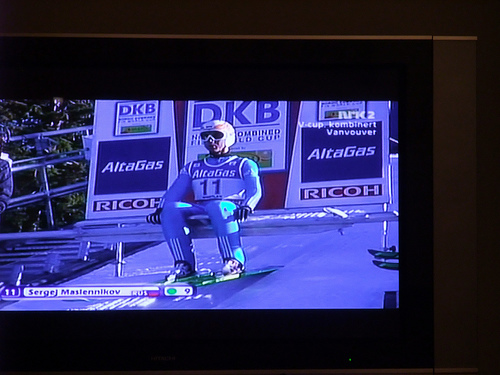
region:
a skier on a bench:
[96, 115, 314, 300]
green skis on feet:
[128, 233, 341, 313]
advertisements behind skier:
[96, 101, 419, 207]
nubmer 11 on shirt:
[186, 177, 238, 213]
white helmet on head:
[193, 110, 236, 148]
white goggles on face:
[198, 129, 232, 143]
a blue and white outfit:
[149, 144, 305, 296]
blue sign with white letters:
[88, 133, 175, 196]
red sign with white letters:
[300, 175, 387, 222]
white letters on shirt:
[185, 165, 239, 180]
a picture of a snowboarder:
[6, 83, 441, 298]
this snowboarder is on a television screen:
[7, 80, 423, 327]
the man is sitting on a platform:
[125, 102, 271, 282]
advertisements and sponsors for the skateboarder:
[91, 97, 396, 217]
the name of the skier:
[1, 275, 206, 295]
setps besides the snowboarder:
[2, 126, 120, 261]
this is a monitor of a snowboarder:
[11, 40, 472, 363]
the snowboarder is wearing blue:
[125, 130, 280, 296]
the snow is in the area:
[82, 253, 357, 311]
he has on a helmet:
[186, 115, 258, 162]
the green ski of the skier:
[155, 272, 202, 288]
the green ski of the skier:
[187, 262, 277, 288]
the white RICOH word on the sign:
[92, 198, 159, 211]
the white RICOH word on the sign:
[299, 181, 383, 203]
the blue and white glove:
[147, 208, 163, 223]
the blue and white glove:
[233, 205, 250, 220]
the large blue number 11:
[198, 176, 221, 198]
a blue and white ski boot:
[168, 260, 190, 281]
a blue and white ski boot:
[218, 253, 245, 273]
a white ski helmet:
[199, 115, 234, 149]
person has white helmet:
[194, 117, 235, 151]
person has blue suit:
[162, 173, 254, 260]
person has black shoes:
[151, 253, 251, 288]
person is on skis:
[151, 264, 266, 288]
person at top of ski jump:
[212, 201, 332, 311]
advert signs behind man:
[98, 101, 395, 188]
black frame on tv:
[0, 41, 430, 362]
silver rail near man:
[20, 135, 88, 232]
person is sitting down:
[100, 204, 354, 251]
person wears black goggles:
[184, 113, 221, 161]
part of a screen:
[408, 295, 421, 309]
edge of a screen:
[425, 283, 435, 298]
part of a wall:
[453, 254, 465, 269]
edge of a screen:
[392, 345, 398, 351]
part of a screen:
[311, 273, 322, 327]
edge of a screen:
[408, 332, 419, 361]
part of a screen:
[349, 320, 357, 340]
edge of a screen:
[258, 240, 272, 255]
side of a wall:
[424, 309, 441, 314]